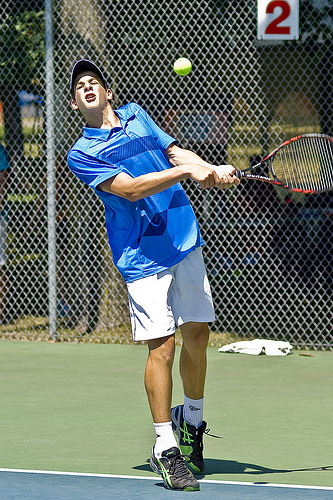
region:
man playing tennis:
[60, 57, 216, 482]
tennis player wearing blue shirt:
[64, 109, 211, 288]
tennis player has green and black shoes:
[147, 402, 221, 490]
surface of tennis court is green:
[29, 357, 114, 443]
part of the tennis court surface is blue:
[30, 443, 114, 489]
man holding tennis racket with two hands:
[189, 122, 329, 203]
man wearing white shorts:
[119, 248, 219, 341]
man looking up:
[65, 54, 110, 101]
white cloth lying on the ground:
[214, 324, 296, 358]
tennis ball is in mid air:
[153, 44, 194, 86]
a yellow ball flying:
[165, 54, 196, 76]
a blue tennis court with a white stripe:
[0, 469, 332, 498]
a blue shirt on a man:
[64, 107, 227, 270]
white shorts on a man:
[106, 228, 212, 339]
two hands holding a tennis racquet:
[198, 146, 254, 195]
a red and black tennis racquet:
[225, 130, 331, 194]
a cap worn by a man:
[65, 56, 118, 111]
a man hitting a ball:
[59, 56, 227, 490]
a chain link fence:
[3, 4, 331, 341]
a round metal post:
[42, 0, 64, 336]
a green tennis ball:
[169, 53, 195, 80]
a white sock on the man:
[152, 421, 182, 460]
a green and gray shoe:
[143, 443, 201, 494]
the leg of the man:
[128, 271, 174, 426]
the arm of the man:
[65, 142, 191, 202]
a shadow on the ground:
[131, 455, 332, 481]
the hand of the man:
[187, 161, 222, 192]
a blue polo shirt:
[65, 99, 211, 286]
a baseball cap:
[63, 57, 108, 96]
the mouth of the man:
[83, 90, 97, 101]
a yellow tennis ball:
[172, 57, 192, 76]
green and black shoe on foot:
[149, 445, 201, 492]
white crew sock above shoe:
[151, 421, 179, 455]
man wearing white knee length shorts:
[123, 244, 216, 340]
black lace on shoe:
[167, 452, 188, 478]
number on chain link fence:
[257, 0, 300, 39]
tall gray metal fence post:
[40, 0, 63, 341]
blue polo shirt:
[67, 104, 208, 280]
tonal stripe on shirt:
[96, 133, 160, 162]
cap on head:
[71, 58, 107, 91]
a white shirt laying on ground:
[216, 329, 300, 366]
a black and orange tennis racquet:
[235, 117, 331, 210]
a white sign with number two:
[253, 0, 300, 45]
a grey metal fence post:
[43, 0, 59, 340]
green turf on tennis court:
[6, 344, 108, 468]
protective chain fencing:
[209, 52, 326, 130]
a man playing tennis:
[48, 27, 326, 306]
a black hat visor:
[58, 51, 118, 87]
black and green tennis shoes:
[137, 394, 225, 492]